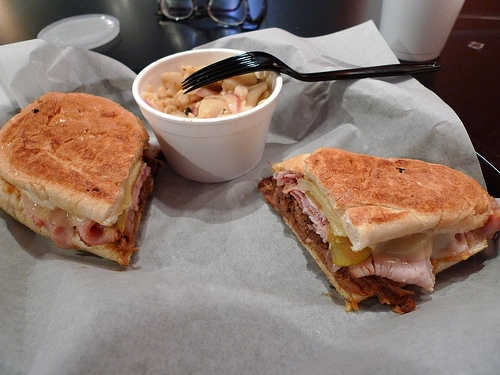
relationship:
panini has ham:
[260, 148, 500, 315] [275, 169, 500, 293]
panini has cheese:
[260, 148, 500, 315] [299, 177, 432, 255]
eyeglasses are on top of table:
[160, 1, 268, 29] [3, 1, 499, 374]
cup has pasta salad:
[133, 46, 281, 185] [142, 61, 274, 119]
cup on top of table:
[133, 46, 281, 185] [3, 1, 499, 374]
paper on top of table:
[0, 19, 499, 372] [3, 1, 499, 374]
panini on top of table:
[260, 148, 500, 315] [3, 1, 499, 374]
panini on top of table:
[0, 92, 161, 265] [3, 1, 499, 374]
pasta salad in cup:
[142, 61, 274, 119] [133, 46, 281, 185]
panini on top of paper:
[260, 148, 500, 315] [0, 19, 499, 372]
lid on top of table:
[37, 13, 120, 51] [3, 1, 499, 374]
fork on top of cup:
[180, 50, 443, 97] [133, 46, 281, 185]